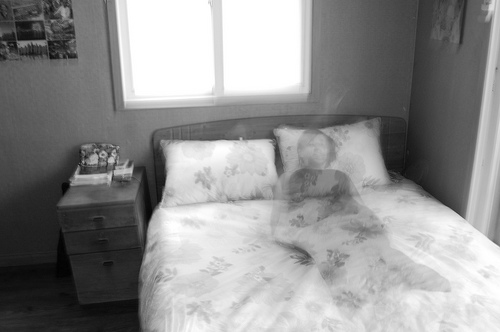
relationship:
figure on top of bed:
[280, 129, 414, 314] [149, 124, 499, 332]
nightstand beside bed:
[60, 168, 146, 317] [149, 124, 499, 332]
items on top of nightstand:
[65, 144, 131, 184] [60, 168, 146, 317]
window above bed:
[105, 1, 320, 103] [149, 124, 499, 332]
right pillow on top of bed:
[274, 114, 391, 201] [149, 124, 499, 332]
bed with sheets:
[149, 124, 499, 332] [152, 174, 493, 331]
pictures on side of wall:
[1, 5, 76, 63] [4, 4, 404, 265]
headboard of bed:
[154, 116, 404, 184] [149, 124, 499, 332]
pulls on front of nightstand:
[91, 214, 118, 269] [60, 168, 146, 317]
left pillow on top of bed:
[275, 124, 385, 185] [149, 124, 499, 332]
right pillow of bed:
[156, 137, 282, 202] [149, 124, 499, 332]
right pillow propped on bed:
[274, 114, 391, 201] [149, 124, 499, 332]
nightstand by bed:
[60, 168, 146, 317] [149, 124, 499, 332]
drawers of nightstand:
[63, 207, 137, 306] [60, 168, 146, 317]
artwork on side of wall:
[431, 4, 464, 41] [410, 3, 483, 207]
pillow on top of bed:
[156, 137, 282, 202] [149, 124, 499, 332]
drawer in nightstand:
[60, 208, 143, 226] [60, 168, 146, 317]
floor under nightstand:
[3, 262, 140, 330] [60, 168, 146, 317]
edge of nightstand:
[126, 169, 145, 208] [60, 168, 146, 317]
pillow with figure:
[275, 124, 385, 185] [280, 129, 414, 314]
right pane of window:
[224, 1, 309, 98] [105, 1, 320, 103]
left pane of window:
[120, 5, 215, 103] [105, 1, 320, 103]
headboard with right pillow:
[154, 116, 404, 184] [274, 114, 391, 201]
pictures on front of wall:
[1, 5, 76, 63] [4, 4, 404, 265]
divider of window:
[207, 3, 227, 99] [105, 1, 320, 103]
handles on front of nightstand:
[91, 214, 118, 269] [60, 168, 146, 317]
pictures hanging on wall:
[1, 5, 76, 63] [4, 4, 404, 265]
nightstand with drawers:
[60, 168, 146, 317] [63, 207, 137, 306]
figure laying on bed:
[280, 129, 414, 314] [149, 124, 499, 332]